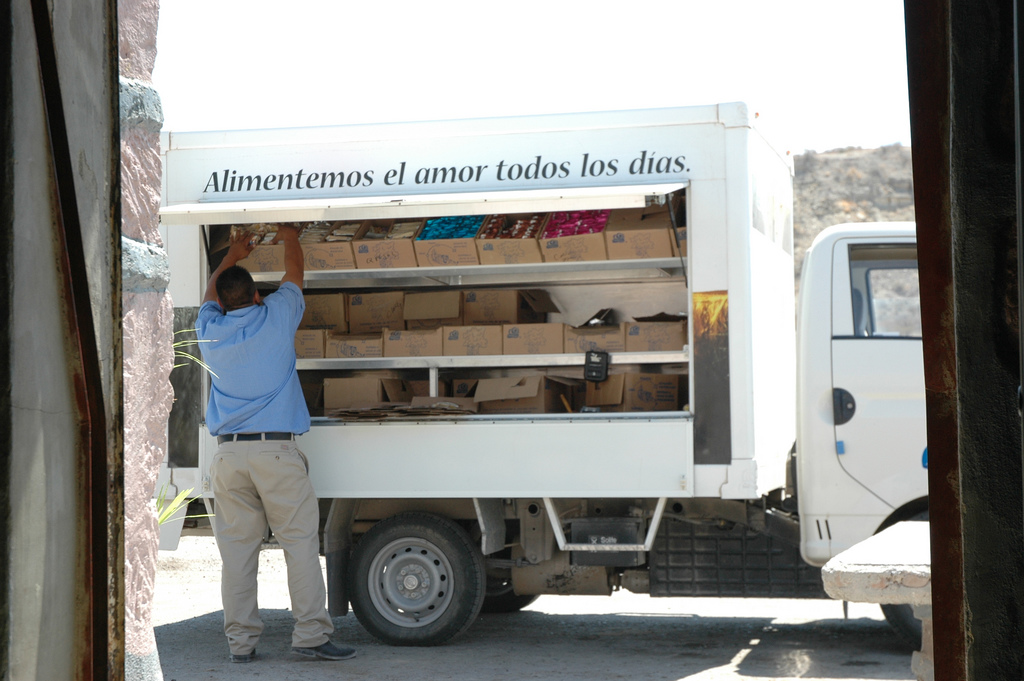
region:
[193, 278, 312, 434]
A blue tee shirt on a man.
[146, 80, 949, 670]
man on front an open van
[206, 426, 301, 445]
a belt on the pants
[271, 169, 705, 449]
boxes inside a van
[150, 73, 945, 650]
the van is color white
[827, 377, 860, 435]
the handle of a door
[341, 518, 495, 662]
the back wheel of a van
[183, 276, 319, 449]
the shirt has long sleeves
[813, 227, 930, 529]
the door of a van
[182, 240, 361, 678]
man wearing a blue shirt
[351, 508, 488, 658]
black tire on the white truck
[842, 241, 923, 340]
window on the door of the truck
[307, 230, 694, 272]
boxes of supplies in the truck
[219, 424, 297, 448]
brown belt around the waist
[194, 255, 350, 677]
man wearing tan dress pants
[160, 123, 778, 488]
truck body full of cardboard boxes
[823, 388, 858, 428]
black door handle on the truck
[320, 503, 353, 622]
mudflap on the truck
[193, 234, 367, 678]
man has short cropped black hair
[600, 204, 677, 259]
A box in a truck.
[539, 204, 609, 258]
A box in a truck.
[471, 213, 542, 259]
A box in a truck.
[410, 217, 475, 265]
A box in a truck.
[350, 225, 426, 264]
A box in a truck.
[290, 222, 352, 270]
A box in a truck.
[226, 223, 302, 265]
A box in a truck.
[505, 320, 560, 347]
A box in a truck.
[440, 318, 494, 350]
a closed cardboard box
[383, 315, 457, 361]
a closed cardboard box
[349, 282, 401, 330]
a closed cardboard box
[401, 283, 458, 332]
a closed cardboard box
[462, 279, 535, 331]
a closed cardboard box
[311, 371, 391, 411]
a closed cardboard box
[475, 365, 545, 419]
a closed cardboard box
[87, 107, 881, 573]
this is a food truck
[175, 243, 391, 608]
the man is reaching in the truck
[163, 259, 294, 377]
the shirt is blue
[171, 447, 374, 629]
the pants are khaki